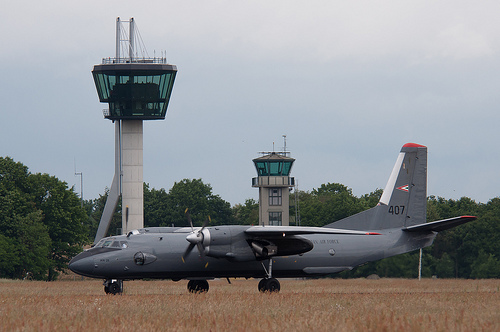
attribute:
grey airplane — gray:
[72, 143, 479, 308]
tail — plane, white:
[373, 142, 483, 254]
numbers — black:
[381, 199, 411, 219]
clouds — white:
[0, 0, 496, 96]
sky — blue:
[3, 3, 497, 206]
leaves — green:
[12, 197, 102, 268]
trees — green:
[2, 158, 109, 281]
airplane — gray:
[75, 140, 472, 298]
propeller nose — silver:
[179, 230, 201, 247]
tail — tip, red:
[370, 136, 460, 244]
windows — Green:
[93, 74, 170, 114]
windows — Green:
[266, 154, 281, 174]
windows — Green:
[282, 157, 291, 177]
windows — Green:
[250, 155, 266, 178]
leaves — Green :
[1, 155, 94, 280]